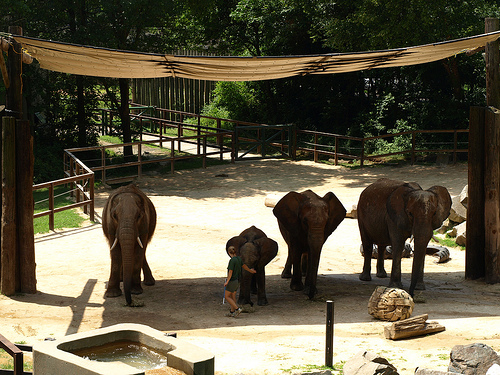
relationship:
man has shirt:
[221, 247, 256, 314] [215, 276, 240, 296]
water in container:
[71, 343, 166, 373] [32, 322, 214, 375]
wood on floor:
[365, 282, 452, 342] [219, 303, 304, 360]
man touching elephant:
[224, 246, 257, 318] [92, 182, 159, 312]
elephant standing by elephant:
[226, 224, 276, 314] [272, 189, 346, 298]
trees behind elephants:
[1, 0, 499, 162] [99, 180, 439, 310]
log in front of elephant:
[383, 313, 446, 339] [352, 174, 453, 290]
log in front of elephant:
[383, 313, 446, 339] [268, 188, 348, 299]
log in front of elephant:
[383, 313, 446, 339] [223, 222, 280, 308]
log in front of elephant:
[383, 313, 446, 339] [101, 182, 159, 306]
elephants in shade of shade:
[91, 171, 475, 308] [221, 220, 483, 313]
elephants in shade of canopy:
[91, 171, 475, 308] [5, 31, 498, 278]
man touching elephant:
[224, 246, 257, 318] [223, 222, 280, 308]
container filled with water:
[20, 307, 188, 374] [81, 344, 154, 362]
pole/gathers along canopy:
[4, 23, 37, 299] [21, 36, 498, 71]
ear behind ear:
[142, 195, 151, 245] [104, 201, 114, 242]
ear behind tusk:
[142, 195, 151, 245] [138, 237, 145, 251]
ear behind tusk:
[142, 195, 151, 245] [109, 237, 118, 252]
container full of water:
[32, 322, 214, 375] [86, 340, 157, 369]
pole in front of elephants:
[322, 300, 337, 368] [17, 129, 482, 331]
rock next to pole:
[349, 350, 474, 372] [310, 280, 352, 373]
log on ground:
[380, 313, 446, 347] [201, 311, 296, 371]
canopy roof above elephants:
[2, 30, 481, 82] [338, 170, 461, 290]